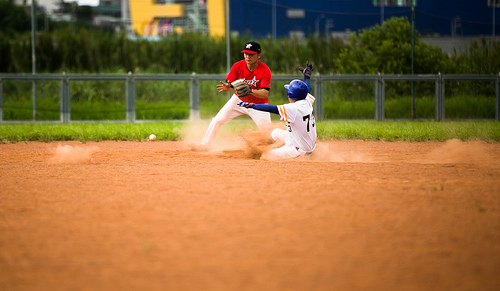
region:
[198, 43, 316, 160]
people are playing baseball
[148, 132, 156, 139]
the ball is white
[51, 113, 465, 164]
dust on the field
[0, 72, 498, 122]
fence is made of metal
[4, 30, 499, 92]
a line of bushes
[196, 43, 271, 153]
getting ready to catch ball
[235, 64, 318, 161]
player sliding to base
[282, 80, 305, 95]
the helmet is blue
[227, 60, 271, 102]
the shirt is red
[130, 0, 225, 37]
yellow painted part of building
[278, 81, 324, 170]
person is playing baseball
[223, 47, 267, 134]
person is playing baseball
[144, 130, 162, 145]
baseball in mid air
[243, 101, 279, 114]
blue sleeve on left arm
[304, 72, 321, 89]
blue sleeve on right arm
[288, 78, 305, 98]
blue baseball helmet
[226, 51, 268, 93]
person is wearing a red shirt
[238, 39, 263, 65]
person is wearing a cap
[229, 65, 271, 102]
baseball is on the right hand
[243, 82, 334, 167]
player sliding into the base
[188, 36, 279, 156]
player waiting to catch the ball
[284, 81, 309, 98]
blue helmet slider is wearing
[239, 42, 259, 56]
black, red, and white hat baseman i swearing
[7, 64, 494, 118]
wall along the outfield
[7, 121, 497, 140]
grass in the outfield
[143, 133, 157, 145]
baseball traveling through the air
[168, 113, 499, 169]
dust created by player sliding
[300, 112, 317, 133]
black numbers on slider's jersey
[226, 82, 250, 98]
glove the baseman is wearing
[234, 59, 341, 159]
Man wearing a white jersey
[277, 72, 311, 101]
Helmet on the man's head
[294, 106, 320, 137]
Black numbers on the jersey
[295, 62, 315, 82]
Glove on the man's hand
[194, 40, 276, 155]
Man wearing a red jersey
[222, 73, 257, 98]
Baseball mitt on the man's hand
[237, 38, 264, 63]
Hat on the man's head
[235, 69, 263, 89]
White letters on the man's jersey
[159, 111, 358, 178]
Dirt in the air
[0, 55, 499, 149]
Fence in the background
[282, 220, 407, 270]
BROWN DIRT ON THE GROUND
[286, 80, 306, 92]
BLUE HELMET ON THE HEAD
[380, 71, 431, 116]
METAL FENCE UP AROUND THE FIELD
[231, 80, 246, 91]
MAN HOLDING A GLOVE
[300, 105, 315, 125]
NUMBERS ON THE BACK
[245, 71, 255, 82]
LOGO ON THE SHIRT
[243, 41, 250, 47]
LOGO ON THE HAT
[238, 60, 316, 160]
person sliding into base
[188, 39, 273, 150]
person in a red jersey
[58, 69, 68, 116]
grey wide fence pole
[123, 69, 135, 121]
grey wide fence pole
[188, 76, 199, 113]
grey wide fence pole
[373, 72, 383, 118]
grey wide fence pole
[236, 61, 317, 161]
baseball player wearing a blue helmet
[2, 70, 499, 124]
fence behind baseball player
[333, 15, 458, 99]
green bush behind fence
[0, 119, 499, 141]
grass growing in front of fence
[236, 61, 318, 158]
baseball player wearing a white jersey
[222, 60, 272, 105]
red short sleeve jersey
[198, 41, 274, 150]
player wearing a baseball glove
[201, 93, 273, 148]
white pants